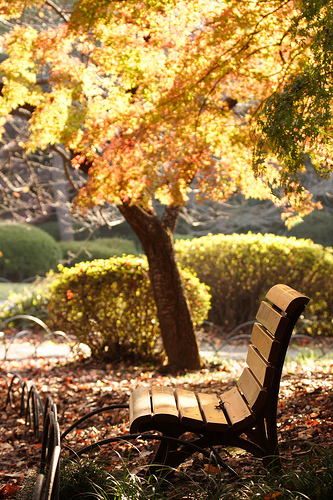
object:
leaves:
[58, 48, 110, 114]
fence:
[0, 369, 65, 499]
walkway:
[195, 335, 331, 364]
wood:
[191, 384, 235, 435]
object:
[214, 399, 228, 410]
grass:
[53, 446, 331, 499]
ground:
[256, 94, 276, 120]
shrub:
[29, 221, 98, 244]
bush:
[47, 252, 211, 361]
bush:
[168, 229, 331, 336]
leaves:
[70, 372, 107, 395]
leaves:
[0, 0, 41, 109]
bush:
[93, 234, 136, 253]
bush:
[57, 238, 117, 261]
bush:
[0, 221, 62, 282]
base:
[142, 415, 285, 482]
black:
[44, 408, 59, 446]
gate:
[11, 371, 42, 418]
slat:
[244, 344, 272, 390]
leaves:
[2, 441, 28, 495]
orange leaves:
[97, 379, 103, 386]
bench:
[128, 283, 311, 477]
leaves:
[158, 171, 190, 210]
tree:
[0, 0, 307, 372]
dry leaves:
[278, 360, 329, 450]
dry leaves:
[0, 354, 133, 453]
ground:
[0, 231, 332, 497]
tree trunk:
[71, 147, 200, 370]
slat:
[264, 283, 307, 310]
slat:
[238, 367, 265, 413]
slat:
[197, 392, 228, 429]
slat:
[151, 385, 180, 421]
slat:
[174, 388, 203, 432]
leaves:
[148, 75, 186, 138]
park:
[1, 0, 332, 498]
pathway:
[2, 334, 331, 373]